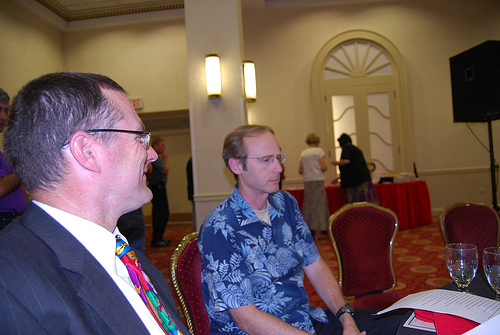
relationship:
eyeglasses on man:
[60, 125, 154, 150] [0, 70, 197, 332]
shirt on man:
[196, 187, 327, 333] [199, 122, 369, 332]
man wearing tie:
[0, 70, 197, 332] [117, 230, 193, 333]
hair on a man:
[11, 66, 125, 196] [0, 70, 197, 332]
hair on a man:
[217, 111, 280, 174] [195, 122, 403, 335]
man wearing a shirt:
[0, 70, 197, 332] [33, 195, 174, 333]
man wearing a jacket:
[0, 70, 197, 332] [4, 193, 189, 333]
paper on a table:
[400, 308, 432, 333] [327, 271, 496, 332]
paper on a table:
[372, 287, 500, 325] [327, 271, 496, 332]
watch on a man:
[331, 300, 358, 320] [199, 122, 369, 332]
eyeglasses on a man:
[60, 125, 154, 150] [0, 70, 197, 332]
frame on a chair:
[169, 222, 207, 332] [324, 190, 414, 317]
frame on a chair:
[326, 195, 402, 293] [437, 186, 497, 286]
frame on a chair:
[437, 195, 495, 276] [167, 219, 216, 333]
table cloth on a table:
[282, 179, 430, 230] [280, 170, 429, 231]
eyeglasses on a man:
[231, 153, 287, 164] [199, 122, 369, 332]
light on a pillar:
[202, 52, 221, 100] [180, 0, 254, 230]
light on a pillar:
[240, 55, 261, 111] [180, 0, 254, 230]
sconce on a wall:
[195, 48, 227, 104] [184, 0, 249, 227]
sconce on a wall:
[242, 51, 258, 114] [184, 0, 249, 227]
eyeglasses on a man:
[231, 144, 291, 171] [195, 122, 403, 335]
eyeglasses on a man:
[73, 122, 165, 145] [0, 70, 197, 332]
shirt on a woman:
[297, 140, 333, 185] [298, 128, 334, 238]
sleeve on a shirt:
[317, 146, 331, 164] [297, 140, 333, 185]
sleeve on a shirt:
[295, 148, 309, 166] [297, 140, 333, 185]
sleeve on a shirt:
[193, 202, 245, 318] [195, 177, 325, 329]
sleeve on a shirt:
[280, 190, 320, 270] [195, 177, 325, 329]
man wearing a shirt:
[195, 122, 403, 335] [195, 177, 325, 329]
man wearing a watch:
[195, 122, 403, 335] [335, 303, 357, 322]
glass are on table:
[444, 242, 479, 294] [362, 261, 494, 332]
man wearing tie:
[0, 70, 197, 335] [111, 233, 196, 333]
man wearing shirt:
[195, 122, 403, 335] [196, 187, 327, 333]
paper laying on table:
[375, 286, 498, 326] [356, 256, 498, 333]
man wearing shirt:
[0, 70, 197, 335] [33, 195, 174, 333]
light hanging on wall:
[202, 49, 223, 100] [182, 7, 246, 137]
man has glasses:
[0, 70, 197, 332] [77, 116, 157, 148]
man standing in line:
[151, 139, 172, 247] [0, 116, 381, 249]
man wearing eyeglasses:
[0, 70, 197, 335] [75, 120, 153, 145]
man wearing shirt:
[199, 122, 369, 332] [196, 187, 327, 333]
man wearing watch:
[199, 122, 369, 332] [328, 302, 357, 322]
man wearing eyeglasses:
[199, 122, 369, 332] [247, 146, 287, 172]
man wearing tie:
[0, 70, 197, 335] [109, 238, 169, 330]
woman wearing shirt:
[330, 131, 390, 226] [334, 141, 369, 172]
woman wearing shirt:
[290, 128, 330, 233] [295, 142, 329, 187]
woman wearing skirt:
[296, 133, 330, 235] [299, 179, 329, 236]